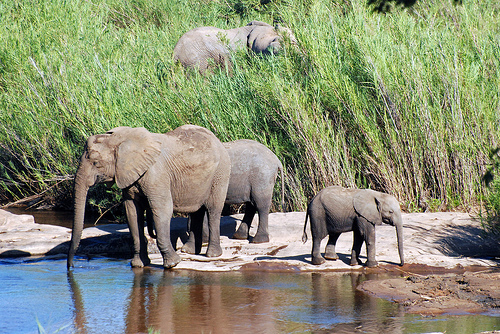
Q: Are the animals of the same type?
A: Yes, all the animals are elephants.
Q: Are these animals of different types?
A: No, all the animals are elephants.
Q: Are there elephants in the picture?
A: Yes, there is an elephant.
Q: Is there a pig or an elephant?
A: Yes, there is an elephant.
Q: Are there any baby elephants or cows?
A: Yes, there is a baby elephant.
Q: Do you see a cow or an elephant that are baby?
A: Yes, the elephant is a baby.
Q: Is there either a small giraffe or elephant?
A: Yes, there is a small elephant.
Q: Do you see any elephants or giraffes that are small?
A: Yes, the elephant is small.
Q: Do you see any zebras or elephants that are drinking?
A: Yes, the elephant is drinking.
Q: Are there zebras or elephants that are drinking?
A: Yes, the elephant is drinking.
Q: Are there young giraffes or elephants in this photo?
A: Yes, there is a young elephant.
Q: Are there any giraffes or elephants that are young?
A: Yes, the elephant is young.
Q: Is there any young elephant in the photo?
A: Yes, there is a young elephant.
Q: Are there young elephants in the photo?
A: Yes, there is a young elephant.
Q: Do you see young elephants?
A: Yes, there is a young elephant.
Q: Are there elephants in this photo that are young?
A: Yes, there is an elephant that is young.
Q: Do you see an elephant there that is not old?
A: Yes, there is an young elephant.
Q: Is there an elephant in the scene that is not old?
A: Yes, there is an young elephant.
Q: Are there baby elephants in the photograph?
A: Yes, there is a baby elephant.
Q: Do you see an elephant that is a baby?
A: Yes, there is an elephant that is a baby.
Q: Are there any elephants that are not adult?
A: Yes, there is an baby elephant.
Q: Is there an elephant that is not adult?
A: Yes, there is an baby elephant.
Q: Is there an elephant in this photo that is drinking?
A: Yes, there is an elephant that is drinking.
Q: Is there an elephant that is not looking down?
A: Yes, there is an elephant that is drinking.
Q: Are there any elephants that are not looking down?
A: Yes, there is an elephant that is drinking.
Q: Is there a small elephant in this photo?
A: Yes, there is a small elephant.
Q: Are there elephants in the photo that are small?
A: Yes, there is an elephant that is small.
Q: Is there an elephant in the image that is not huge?
A: Yes, there is a small elephant.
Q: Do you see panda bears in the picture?
A: No, there are no panda bears.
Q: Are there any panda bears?
A: No, there are no panda bears.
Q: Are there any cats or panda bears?
A: No, there are no panda bears or cats.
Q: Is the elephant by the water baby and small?
A: Yes, the elephant is a baby and small.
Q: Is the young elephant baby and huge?
A: No, the elephant is a baby but small.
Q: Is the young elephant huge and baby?
A: No, the elephant is a baby but small.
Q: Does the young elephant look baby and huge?
A: No, the elephant is a baby but small.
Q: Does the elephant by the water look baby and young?
A: Yes, the elephant is a baby and young.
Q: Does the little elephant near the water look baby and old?
A: No, the elephant is a baby but young.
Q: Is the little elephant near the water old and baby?
A: No, the elephant is a baby but young.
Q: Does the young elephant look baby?
A: Yes, the elephant is a baby.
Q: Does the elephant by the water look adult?
A: No, the elephant is a baby.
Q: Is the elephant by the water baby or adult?
A: The elephant is a baby.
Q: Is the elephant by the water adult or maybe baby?
A: The elephant is a baby.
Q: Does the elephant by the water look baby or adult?
A: The elephant is a baby.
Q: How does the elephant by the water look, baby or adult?
A: The elephant is a baby.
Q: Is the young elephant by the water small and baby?
A: Yes, the elephant is small and baby.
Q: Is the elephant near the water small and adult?
A: No, the elephant is small but baby.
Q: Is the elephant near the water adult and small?
A: No, the elephant is small but baby.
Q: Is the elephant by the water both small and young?
A: Yes, the elephant is small and young.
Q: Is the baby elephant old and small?
A: No, the elephant is small but young.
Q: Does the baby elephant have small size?
A: Yes, the elephant is small.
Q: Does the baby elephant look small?
A: Yes, the elephant is small.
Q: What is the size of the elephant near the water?
A: The elephant is small.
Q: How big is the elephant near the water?
A: The elephant is small.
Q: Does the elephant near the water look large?
A: No, the elephant is small.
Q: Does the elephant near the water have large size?
A: No, the elephant is small.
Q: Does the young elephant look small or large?
A: The elephant is small.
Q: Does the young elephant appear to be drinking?
A: Yes, the elephant is drinking.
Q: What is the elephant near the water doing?
A: The elephant is drinking.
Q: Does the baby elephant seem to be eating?
A: No, the elephant is drinking.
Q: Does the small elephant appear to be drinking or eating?
A: The elephant is drinking.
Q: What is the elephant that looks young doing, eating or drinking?
A: The elephant is drinking.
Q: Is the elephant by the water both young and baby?
A: Yes, the elephant is young and baby.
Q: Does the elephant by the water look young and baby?
A: Yes, the elephant is young and baby.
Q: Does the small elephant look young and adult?
A: No, the elephant is young but baby.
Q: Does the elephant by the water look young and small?
A: Yes, the elephant is young and small.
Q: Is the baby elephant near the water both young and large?
A: No, the elephant is young but small.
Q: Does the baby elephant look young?
A: Yes, the elephant is young.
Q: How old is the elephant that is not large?
A: The elephant is young.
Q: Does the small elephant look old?
A: No, the elephant is young.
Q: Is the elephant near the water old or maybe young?
A: The elephant is young.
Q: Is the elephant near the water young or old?
A: The elephant is young.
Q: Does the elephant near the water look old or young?
A: The elephant is young.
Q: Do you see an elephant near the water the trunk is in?
A: Yes, there is an elephant near the water.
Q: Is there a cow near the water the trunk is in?
A: No, there is an elephant near the water.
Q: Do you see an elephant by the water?
A: Yes, there is an elephant by the water.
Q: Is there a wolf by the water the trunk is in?
A: No, there is an elephant by the water.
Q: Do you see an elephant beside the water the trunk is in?
A: Yes, there is an elephant beside the water.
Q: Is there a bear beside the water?
A: No, there is an elephant beside the water.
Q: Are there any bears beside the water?
A: No, there is an elephant beside the water.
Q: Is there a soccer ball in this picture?
A: No, there are no soccer balls.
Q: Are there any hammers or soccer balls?
A: No, there are no soccer balls or hammers.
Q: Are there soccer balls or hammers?
A: No, there are no soccer balls or hammers.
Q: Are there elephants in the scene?
A: Yes, there is an elephant.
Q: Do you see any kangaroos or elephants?
A: Yes, there is an elephant.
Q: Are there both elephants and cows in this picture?
A: No, there is an elephant but no cows.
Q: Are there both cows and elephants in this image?
A: No, there is an elephant but no cows.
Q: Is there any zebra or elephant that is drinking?
A: Yes, the elephant is drinking.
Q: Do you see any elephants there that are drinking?
A: Yes, there is an elephant that is drinking.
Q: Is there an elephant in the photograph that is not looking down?
A: Yes, there is an elephant that is drinking.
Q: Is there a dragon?
A: No, there are no dragons.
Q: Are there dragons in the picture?
A: No, there are no dragons.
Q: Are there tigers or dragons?
A: No, there are no dragons or tigers.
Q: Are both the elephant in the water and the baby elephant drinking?
A: Yes, both the elephant and the elephant are drinking.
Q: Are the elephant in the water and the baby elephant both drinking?
A: Yes, both the elephant and the elephant are drinking.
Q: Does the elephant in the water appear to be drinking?
A: Yes, the elephant is drinking.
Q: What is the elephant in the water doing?
A: The elephant is drinking.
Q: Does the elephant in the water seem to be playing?
A: No, the elephant is drinking.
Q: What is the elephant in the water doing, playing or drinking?
A: The elephant is drinking.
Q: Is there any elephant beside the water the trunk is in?
A: Yes, there is an elephant beside the water.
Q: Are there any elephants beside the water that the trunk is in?
A: Yes, there is an elephant beside the water.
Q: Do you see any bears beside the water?
A: No, there is an elephant beside the water.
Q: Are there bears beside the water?
A: No, there is an elephant beside the water.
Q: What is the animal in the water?
A: The animal is an elephant.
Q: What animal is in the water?
A: The animal is an elephant.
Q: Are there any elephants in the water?
A: Yes, there is an elephant in the water.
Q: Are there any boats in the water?
A: No, there is an elephant in the water.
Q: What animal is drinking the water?
A: The elephant is drinking the water.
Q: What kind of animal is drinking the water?
A: The animal is an elephant.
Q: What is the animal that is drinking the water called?
A: The animal is an elephant.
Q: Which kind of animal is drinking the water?
A: The animal is an elephant.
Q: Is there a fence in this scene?
A: No, there are no fences.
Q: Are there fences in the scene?
A: No, there are no fences.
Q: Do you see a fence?
A: No, there are no fences.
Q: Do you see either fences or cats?
A: No, there are no fences or cats.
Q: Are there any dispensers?
A: No, there are no dispensers.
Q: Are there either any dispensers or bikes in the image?
A: No, there are no dispensers or bikes.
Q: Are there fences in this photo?
A: No, there are no fences.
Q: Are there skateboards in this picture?
A: No, there are no skateboards.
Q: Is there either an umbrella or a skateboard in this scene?
A: No, there are no skateboards or umbrellas.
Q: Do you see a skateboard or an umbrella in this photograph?
A: No, there are no skateboards or umbrellas.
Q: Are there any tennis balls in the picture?
A: No, there are no tennis balls.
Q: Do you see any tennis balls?
A: No, there are no tennis balls.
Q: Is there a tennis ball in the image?
A: No, there are no tennis balls.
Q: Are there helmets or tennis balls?
A: No, there are no tennis balls or helmets.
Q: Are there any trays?
A: No, there are no trays.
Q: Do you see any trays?
A: No, there are no trays.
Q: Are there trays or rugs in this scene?
A: No, there are no trays or rugs.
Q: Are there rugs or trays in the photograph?
A: No, there are no trays or rugs.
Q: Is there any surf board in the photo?
A: No, there are no surfboards.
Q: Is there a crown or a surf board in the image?
A: No, there are no surfboards or crowns.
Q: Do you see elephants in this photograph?
A: Yes, there is an elephant.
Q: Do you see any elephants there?
A: Yes, there is an elephant.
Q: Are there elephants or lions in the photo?
A: Yes, there is an elephant.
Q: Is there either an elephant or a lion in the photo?
A: Yes, there is an elephant.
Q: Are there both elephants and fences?
A: No, there is an elephant but no fences.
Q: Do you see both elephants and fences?
A: No, there is an elephant but no fences.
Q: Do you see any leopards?
A: No, there are no leopards.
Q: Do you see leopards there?
A: No, there are no leopards.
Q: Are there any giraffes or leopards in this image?
A: No, there are no leopards or giraffes.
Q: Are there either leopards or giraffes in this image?
A: No, there are no leopards or giraffes.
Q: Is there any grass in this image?
A: Yes, there is grass.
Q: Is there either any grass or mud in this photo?
A: Yes, there is grass.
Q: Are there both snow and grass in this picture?
A: No, there is grass but no snow.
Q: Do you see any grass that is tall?
A: Yes, there is tall grass.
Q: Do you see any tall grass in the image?
A: Yes, there is tall grass.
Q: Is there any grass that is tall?
A: Yes, there is grass that is tall.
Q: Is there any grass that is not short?
A: Yes, there is tall grass.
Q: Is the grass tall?
A: Yes, the grass is tall.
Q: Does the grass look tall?
A: Yes, the grass is tall.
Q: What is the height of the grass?
A: The grass is tall.